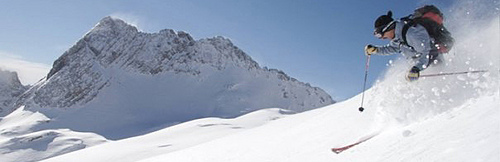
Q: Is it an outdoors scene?
A: Yes, it is outdoors.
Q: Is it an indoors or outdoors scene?
A: It is outdoors.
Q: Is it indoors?
A: No, it is outdoors.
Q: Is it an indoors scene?
A: No, it is outdoors.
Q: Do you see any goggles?
A: Yes, there are goggles.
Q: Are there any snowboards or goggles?
A: Yes, there are goggles.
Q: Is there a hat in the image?
A: Yes, there is a hat.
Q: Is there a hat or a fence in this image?
A: Yes, there is a hat.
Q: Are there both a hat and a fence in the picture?
A: No, there is a hat but no fences.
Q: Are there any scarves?
A: No, there are no scarves.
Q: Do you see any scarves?
A: No, there are no scarves.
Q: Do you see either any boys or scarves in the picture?
A: No, there are no scarves or boys.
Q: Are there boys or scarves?
A: No, there are no scarves or boys.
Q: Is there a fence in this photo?
A: No, there are no fences.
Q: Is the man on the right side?
A: Yes, the man is on the right of the image.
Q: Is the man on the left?
A: No, the man is on the right of the image.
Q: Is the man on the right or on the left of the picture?
A: The man is on the right of the image.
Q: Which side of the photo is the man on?
A: The man is on the right of the image.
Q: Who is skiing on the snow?
A: The man is skiing on the snow.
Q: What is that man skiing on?
A: The man is skiing on the snow.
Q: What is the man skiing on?
A: The man is skiing on the snow.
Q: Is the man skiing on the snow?
A: Yes, the man is skiing on the snow.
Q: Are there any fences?
A: No, there are no fences.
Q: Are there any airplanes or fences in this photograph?
A: No, there are no fences or airplanes.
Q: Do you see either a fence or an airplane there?
A: No, there are no fences or airplanes.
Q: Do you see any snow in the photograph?
A: Yes, there is snow.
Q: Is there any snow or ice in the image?
A: Yes, there is snow.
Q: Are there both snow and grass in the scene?
A: No, there is snow but no grass.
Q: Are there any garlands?
A: No, there are no garlands.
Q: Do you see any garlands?
A: No, there are no garlands.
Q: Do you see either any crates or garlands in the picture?
A: No, there are no garlands or crates.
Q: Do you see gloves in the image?
A: Yes, there are gloves.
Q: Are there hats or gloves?
A: Yes, there are gloves.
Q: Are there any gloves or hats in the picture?
A: Yes, there are gloves.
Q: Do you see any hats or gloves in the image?
A: Yes, there are gloves.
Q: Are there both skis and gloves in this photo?
A: Yes, there are both gloves and skis.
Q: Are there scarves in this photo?
A: No, there are no scarves.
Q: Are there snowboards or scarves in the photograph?
A: No, there are no scarves or snowboards.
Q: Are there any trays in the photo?
A: No, there are no trays.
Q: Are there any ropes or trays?
A: No, there are no trays or ropes.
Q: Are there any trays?
A: No, there are no trays.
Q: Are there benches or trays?
A: No, there are no trays or benches.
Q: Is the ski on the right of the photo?
A: Yes, the ski is on the right of the image.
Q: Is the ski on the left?
A: No, the ski is on the right of the image.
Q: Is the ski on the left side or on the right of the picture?
A: The ski is on the right of the image.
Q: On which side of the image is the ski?
A: The ski is on the right of the image.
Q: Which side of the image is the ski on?
A: The ski is on the right of the image.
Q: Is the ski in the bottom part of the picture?
A: Yes, the ski is in the bottom of the image.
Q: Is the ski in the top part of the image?
A: No, the ski is in the bottom of the image.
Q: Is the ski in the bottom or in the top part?
A: The ski is in the bottom of the image.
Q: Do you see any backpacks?
A: Yes, there is a backpack.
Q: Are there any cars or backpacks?
A: Yes, there is a backpack.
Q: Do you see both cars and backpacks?
A: No, there is a backpack but no cars.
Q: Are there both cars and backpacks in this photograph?
A: No, there is a backpack but no cars.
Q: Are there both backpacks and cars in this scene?
A: No, there is a backpack but no cars.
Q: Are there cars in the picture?
A: No, there are no cars.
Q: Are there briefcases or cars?
A: No, there are no cars or briefcases.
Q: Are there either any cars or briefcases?
A: No, there are no cars or briefcases.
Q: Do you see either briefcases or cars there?
A: No, there are no cars or briefcases.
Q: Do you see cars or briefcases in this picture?
A: No, there are no cars or briefcases.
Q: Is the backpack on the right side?
A: Yes, the backpack is on the right of the image.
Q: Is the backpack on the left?
A: No, the backpack is on the right of the image.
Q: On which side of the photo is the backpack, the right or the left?
A: The backpack is on the right of the image.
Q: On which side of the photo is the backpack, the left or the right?
A: The backpack is on the right of the image.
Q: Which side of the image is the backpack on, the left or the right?
A: The backpack is on the right of the image.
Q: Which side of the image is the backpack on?
A: The backpack is on the right of the image.